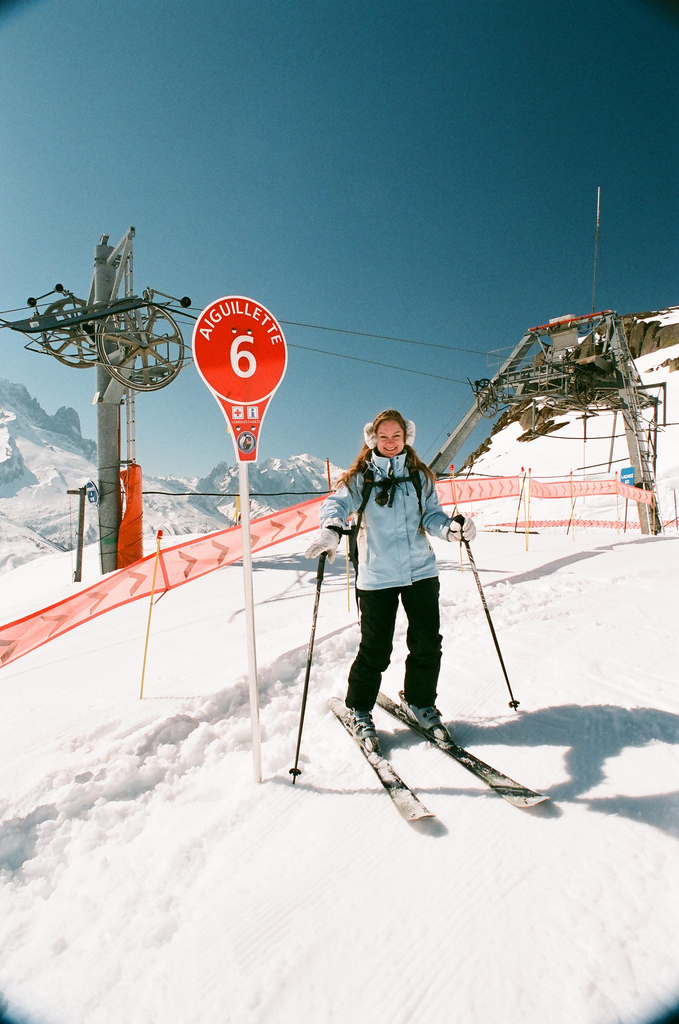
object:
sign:
[191, 295, 289, 464]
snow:
[393, 785, 426, 817]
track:
[0, 621, 362, 890]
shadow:
[262, 704, 679, 841]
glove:
[304, 517, 344, 564]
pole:
[288, 548, 330, 784]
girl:
[305, 406, 477, 753]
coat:
[319, 449, 454, 592]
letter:
[200, 329, 211, 342]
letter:
[204, 318, 215, 327]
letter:
[209, 309, 222, 323]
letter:
[219, 302, 230, 316]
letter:
[231, 302, 236, 315]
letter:
[245, 302, 252, 316]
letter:
[252, 307, 262, 323]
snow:
[0, 307, 679, 1024]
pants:
[345, 577, 444, 714]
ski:
[327, 696, 436, 820]